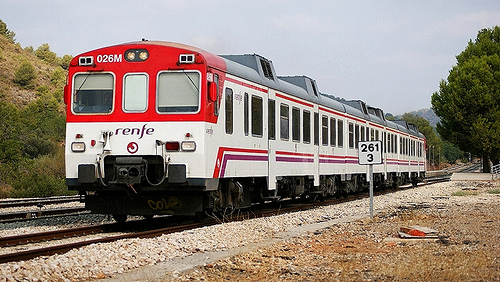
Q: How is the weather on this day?
A: It is cloudy.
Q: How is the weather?
A: It is cloudy.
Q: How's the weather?
A: It is cloudy.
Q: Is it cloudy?
A: Yes, it is cloudy.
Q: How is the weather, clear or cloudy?
A: It is cloudy.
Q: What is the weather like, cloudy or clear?
A: It is cloudy.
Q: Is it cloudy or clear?
A: It is cloudy.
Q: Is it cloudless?
A: No, it is cloudy.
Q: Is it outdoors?
A: Yes, it is outdoors.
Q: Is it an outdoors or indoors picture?
A: It is outdoors.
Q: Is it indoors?
A: No, it is outdoors.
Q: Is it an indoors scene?
A: No, it is outdoors.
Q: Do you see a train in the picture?
A: Yes, there is a train.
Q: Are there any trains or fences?
A: Yes, there is a train.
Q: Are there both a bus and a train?
A: No, there is a train but no buses.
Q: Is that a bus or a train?
A: That is a train.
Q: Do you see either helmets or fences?
A: No, there are no fences or helmets.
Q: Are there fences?
A: No, there are no fences.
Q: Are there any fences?
A: No, there are no fences.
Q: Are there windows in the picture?
A: Yes, there is a window.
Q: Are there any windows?
A: Yes, there is a window.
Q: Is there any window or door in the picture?
A: Yes, there is a window.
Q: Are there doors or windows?
A: Yes, there is a window.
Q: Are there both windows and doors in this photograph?
A: Yes, there are both a window and a door.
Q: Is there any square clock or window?
A: Yes, there is a square window.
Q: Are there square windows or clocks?
A: Yes, there is a square window.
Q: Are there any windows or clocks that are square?
A: Yes, the window is square.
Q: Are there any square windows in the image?
A: Yes, there is a square window.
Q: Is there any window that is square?
A: Yes, there is a window that is square.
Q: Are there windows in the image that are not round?
A: Yes, there is a square window.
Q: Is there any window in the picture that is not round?
A: Yes, there is a square window.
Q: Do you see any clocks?
A: No, there are no clocks.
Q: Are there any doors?
A: Yes, there is a door.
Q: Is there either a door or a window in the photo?
A: Yes, there is a door.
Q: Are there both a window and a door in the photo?
A: Yes, there are both a door and a window.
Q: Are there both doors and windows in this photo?
A: Yes, there are both a door and a window.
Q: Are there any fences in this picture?
A: No, there are no fences.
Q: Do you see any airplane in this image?
A: No, there are no airplanes.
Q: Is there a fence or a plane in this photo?
A: No, there are no airplanes or fences.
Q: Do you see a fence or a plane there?
A: No, there are no airplanes or fences.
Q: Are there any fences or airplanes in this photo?
A: No, there are no airplanes or fences.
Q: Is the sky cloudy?
A: Yes, the sky is cloudy.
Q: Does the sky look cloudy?
A: Yes, the sky is cloudy.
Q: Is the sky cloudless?
A: No, the sky is cloudy.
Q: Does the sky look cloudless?
A: No, the sky is cloudy.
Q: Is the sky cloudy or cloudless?
A: The sky is cloudy.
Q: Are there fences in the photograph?
A: No, there are no fences.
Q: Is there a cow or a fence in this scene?
A: No, there are no fences or cows.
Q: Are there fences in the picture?
A: No, there are no fences.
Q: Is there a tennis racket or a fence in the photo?
A: No, there are no fences or rackets.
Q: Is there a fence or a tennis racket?
A: No, there are no fences or rackets.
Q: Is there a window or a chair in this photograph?
A: Yes, there is a window.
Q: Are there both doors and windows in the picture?
A: Yes, there are both a window and a door.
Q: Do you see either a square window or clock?
A: Yes, there is a square window.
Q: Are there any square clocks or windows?
A: Yes, there is a square window.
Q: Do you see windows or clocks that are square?
A: Yes, the window is square.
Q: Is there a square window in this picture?
A: Yes, there is a square window.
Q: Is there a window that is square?
A: Yes, there is a window that is square.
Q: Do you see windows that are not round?
A: Yes, there is a square window.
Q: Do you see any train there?
A: Yes, there is a train.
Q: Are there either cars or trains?
A: Yes, there is a train.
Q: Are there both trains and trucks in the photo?
A: No, there is a train but no trucks.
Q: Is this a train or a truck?
A: This is a train.